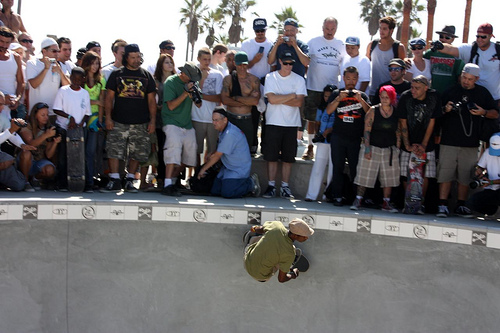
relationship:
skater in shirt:
[228, 202, 323, 281] [242, 219, 296, 287]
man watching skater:
[240, 217, 320, 284] [239, 202, 317, 287]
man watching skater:
[240, 217, 320, 284] [241, 212, 324, 289]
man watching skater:
[240, 217, 320, 284] [239, 205, 326, 291]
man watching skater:
[240, 217, 320, 284] [246, 206, 316, 293]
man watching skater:
[240, 217, 320, 284] [244, 201, 320, 288]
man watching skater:
[240, 217, 320, 284] [238, 210, 318, 290]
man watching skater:
[240, 217, 320, 284] [232, 200, 322, 286]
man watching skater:
[240, 217, 320, 284] [236, 210, 316, 281]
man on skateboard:
[240, 217, 320, 284] [244, 220, 307, 284]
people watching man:
[6, 5, 478, 210] [240, 201, 320, 284]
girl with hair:
[355, 83, 407, 198] [380, 83, 402, 103]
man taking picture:
[164, 60, 204, 182] [7, 8, 484, 294]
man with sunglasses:
[255, 40, 305, 190] [278, 61, 294, 70]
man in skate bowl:
[240, 217, 320, 284] [4, 184, 498, 331]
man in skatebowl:
[240, 217, 320, 284] [6, 186, 484, 326]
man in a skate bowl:
[240, 217, 320, 284] [4, 184, 498, 331]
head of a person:
[121, 42, 143, 72] [103, 46, 160, 192]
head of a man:
[154, 53, 176, 83] [159, 62, 203, 197]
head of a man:
[210, 108, 235, 142] [196, 105, 262, 200]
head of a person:
[284, 219, 309, 253] [241, 215, 311, 289]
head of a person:
[375, 84, 395, 113] [355, 79, 411, 215]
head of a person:
[412, 75, 428, 100] [399, 75, 433, 205]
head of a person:
[382, 54, 409, 84] [366, 57, 411, 109]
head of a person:
[455, 68, 484, 95] [435, 59, 491, 199]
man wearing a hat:
[240, 217, 320, 284] [284, 215, 313, 236]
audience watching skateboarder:
[6, 8, 498, 220] [235, 204, 311, 284]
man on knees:
[196, 105, 262, 200] [199, 168, 224, 195]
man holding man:
[55, 68, 96, 191] [53, 65, 96, 193]